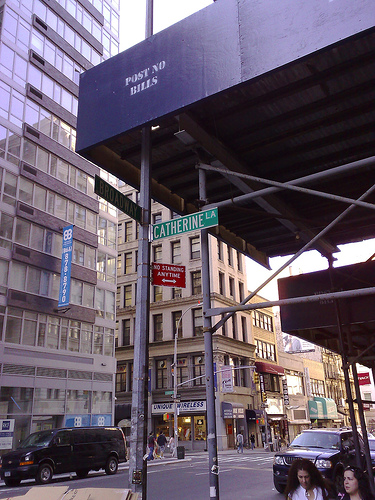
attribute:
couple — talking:
[340, 466, 371, 500]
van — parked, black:
[2, 425, 129, 482]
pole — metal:
[129, 129, 153, 500]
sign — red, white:
[151, 262, 188, 290]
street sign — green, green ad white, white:
[151, 206, 220, 241]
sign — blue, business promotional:
[58, 227, 75, 312]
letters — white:
[126, 58, 167, 96]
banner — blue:
[78, 0, 238, 153]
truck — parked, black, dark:
[273, 427, 374, 468]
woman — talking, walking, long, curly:
[285, 459, 329, 499]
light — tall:
[171, 295, 205, 457]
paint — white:
[219, 453, 275, 471]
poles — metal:
[198, 162, 219, 500]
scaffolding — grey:
[199, 160, 374, 207]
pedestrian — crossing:
[232, 429, 246, 455]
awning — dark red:
[255, 362, 287, 378]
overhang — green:
[309, 397, 340, 422]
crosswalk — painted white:
[217, 452, 275, 465]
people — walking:
[147, 429, 175, 460]